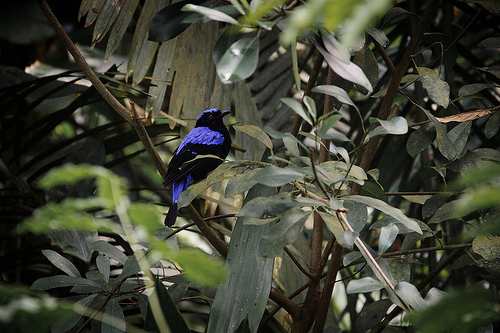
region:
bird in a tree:
[152, 99, 244, 237]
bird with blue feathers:
[162, 106, 244, 233]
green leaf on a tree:
[38, 246, 83, 281]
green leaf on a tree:
[94, 246, 113, 285]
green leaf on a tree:
[100, 290, 132, 331]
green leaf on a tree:
[237, 161, 314, 193]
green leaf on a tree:
[338, 190, 422, 240]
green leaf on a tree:
[371, 220, 404, 262]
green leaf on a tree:
[345, 273, 395, 303]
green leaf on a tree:
[366, 111, 414, 139]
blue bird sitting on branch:
[154, 100, 236, 213]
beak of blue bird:
[220, 107, 233, 117]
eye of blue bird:
[205, 111, 215, 116]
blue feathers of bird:
[167, 123, 224, 223]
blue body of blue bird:
[174, 125, 225, 185]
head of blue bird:
[193, 102, 230, 125]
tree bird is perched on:
[49, 8, 463, 319]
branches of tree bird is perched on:
[61, 9, 423, 305]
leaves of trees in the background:
[31, 5, 464, 305]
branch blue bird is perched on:
[58, 17, 283, 309]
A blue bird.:
[163, 109, 235, 223]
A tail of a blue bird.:
[163, 183, 178, 228]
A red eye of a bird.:
[207, 111, 214, 119]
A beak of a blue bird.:
[220, 110, 230, 117]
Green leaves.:
[222, 92, 426, 244]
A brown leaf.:
[410, 96, 499, 123]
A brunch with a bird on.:
[36, 0, 298, 313]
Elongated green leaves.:
[210, 151, 282, 329]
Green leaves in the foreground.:
[18, 161, 222, 331]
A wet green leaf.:
[213, 30, 260, 87]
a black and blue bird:
[159, 106, 232, 227]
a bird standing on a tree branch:
[115, 106, 232, 227]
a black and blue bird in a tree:
[6, 3, 495, 330]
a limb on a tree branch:
[36, 1, 160, 179]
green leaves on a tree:
[247, 0, 499, 331]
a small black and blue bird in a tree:
[5, 2, 496, 329]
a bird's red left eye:
[205, 112, 214, 122]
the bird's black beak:
[220, 106, 234, 118]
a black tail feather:
[162, 203, 179, 227]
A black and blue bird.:
[163, 107, 235, 227]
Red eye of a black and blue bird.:
[206, 112, 214, 120]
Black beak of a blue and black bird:
[219, 108, 230, 118]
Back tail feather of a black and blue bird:
[161, 177, 193, 227]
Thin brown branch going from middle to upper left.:
[36, 0, 298, 320]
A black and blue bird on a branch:
[163, 103, 233, 227]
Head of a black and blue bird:
[196, 107, 233, 126]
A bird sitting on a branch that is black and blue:
[165, 104, 233, 224]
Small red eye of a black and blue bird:
[206, 113, 216, 121]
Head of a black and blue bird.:
[196, 105, 227, 127]